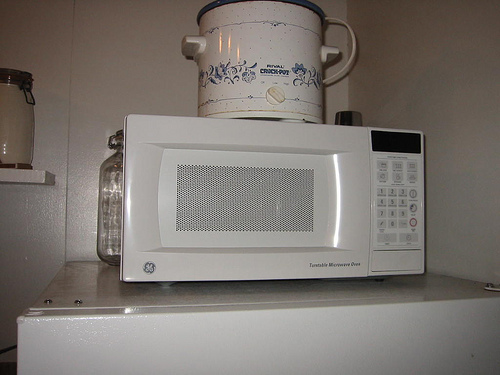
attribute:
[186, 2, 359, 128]
cooker — white, blue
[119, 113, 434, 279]
microwave — white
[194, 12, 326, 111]
croc pot — large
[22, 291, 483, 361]
counter — white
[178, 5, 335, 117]
croc pot — white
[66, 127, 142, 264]
jar — clear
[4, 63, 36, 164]
container — tan